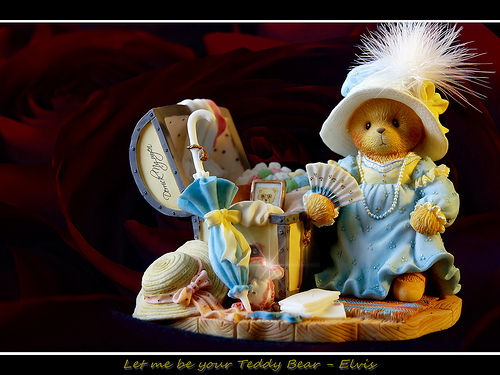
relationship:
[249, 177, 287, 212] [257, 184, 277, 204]
framed photo of bear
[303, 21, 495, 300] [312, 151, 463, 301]
teddy bear wearing dress